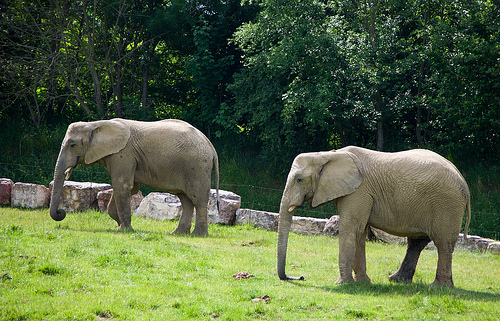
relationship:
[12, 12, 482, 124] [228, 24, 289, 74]
trees with leaves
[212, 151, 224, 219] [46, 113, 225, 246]
tail of elephant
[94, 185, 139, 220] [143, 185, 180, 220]
stone next to stone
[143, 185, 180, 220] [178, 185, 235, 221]
stone next to stone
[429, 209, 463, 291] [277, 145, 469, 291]
legs of elephant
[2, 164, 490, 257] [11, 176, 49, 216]
wall made of stone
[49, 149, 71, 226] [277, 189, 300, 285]
elephant trunks on elephant trunks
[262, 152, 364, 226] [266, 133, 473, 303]
head of elephant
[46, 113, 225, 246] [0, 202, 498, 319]
elephant in field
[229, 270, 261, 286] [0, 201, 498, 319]
droppings on ground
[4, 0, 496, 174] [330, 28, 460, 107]
trees covered in leaves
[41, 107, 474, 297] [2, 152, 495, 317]
elephants walking in field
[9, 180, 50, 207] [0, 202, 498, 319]
rocks on edge field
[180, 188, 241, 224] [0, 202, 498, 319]
rocks on edge field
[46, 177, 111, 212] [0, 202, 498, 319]
rocks on edge field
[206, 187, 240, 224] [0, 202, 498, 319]
rocks on edge field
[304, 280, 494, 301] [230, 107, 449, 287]
shadow of elephant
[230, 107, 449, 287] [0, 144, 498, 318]
elephant on ground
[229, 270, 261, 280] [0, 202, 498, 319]
droppings on field